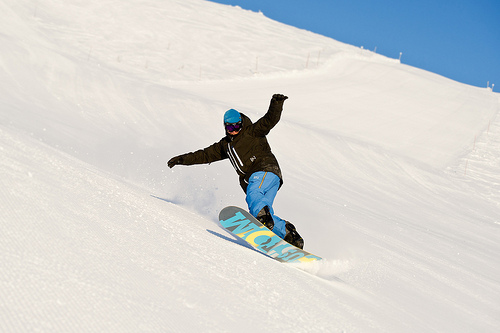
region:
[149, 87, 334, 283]
person riding a snow board in the snow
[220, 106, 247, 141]
blue hat and black goggles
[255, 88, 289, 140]
arm of a person on a snowboard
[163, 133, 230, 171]
arm of a person on a snowboard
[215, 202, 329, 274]
snowboard with writing on the bottom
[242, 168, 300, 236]
pair of blue snow pants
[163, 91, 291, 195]
black and white snow coat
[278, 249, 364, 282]
small plume of snow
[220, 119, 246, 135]
pair of black snow goggles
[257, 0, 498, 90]
sky is blue with no clouds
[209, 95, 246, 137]
head of a person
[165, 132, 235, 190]
arm of a person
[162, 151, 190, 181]
hand of a person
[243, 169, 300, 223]
leg of a person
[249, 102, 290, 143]
arm of a person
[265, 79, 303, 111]
hand of a person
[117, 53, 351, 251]
person wearing a jacket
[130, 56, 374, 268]
person on a snowbaord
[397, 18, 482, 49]
clear blue skies with no clouds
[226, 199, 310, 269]
The person is snowboarding.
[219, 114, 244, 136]
The person is wearing goggles.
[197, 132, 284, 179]
Person is wearing a black jacket.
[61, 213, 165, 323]
Snow on the ground.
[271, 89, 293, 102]
The person is wearing gloves.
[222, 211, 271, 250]
Blue and yellow writing on the snowboard.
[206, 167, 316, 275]
Person is riding snowboard on slope.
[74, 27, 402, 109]
The snow is fluffy.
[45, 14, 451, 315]
person snow boarding down hill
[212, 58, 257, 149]
person wearing a blue hat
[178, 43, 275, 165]
person wearing blue hat and black goggles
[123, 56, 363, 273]
person wearing blue snow pants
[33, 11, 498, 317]
giant ski hill of snow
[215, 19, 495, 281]
a wide path for snow boarding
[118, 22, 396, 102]
orange markers for side of paths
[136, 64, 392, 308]
person balancing as they ski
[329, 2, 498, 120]
blue skies above the snow hill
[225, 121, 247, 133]
goggles on a person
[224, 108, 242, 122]
a blue hat on a person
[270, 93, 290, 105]
a black glove on a person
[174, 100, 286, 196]
a black coat on a person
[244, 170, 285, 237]
blue pants on a person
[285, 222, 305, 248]
a black boot on a person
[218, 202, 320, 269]
a black, white, and yellow snowboard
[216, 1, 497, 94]
a clear blue sky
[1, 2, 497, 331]
a snowy white slope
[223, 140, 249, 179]
white stripes on the front of a coat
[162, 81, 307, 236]
a person is standing up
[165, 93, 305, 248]
a person is playing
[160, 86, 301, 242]
a person is snowboarding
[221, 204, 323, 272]
a snowboard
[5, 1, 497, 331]
snow